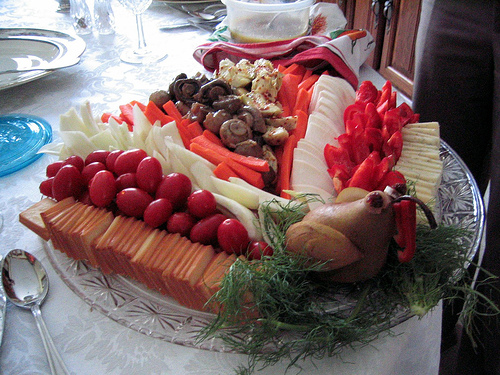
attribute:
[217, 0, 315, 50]
container — clear plastic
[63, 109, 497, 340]
platter — large, glass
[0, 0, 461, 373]
table cloth — white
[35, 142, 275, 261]
olives — red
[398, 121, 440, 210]
cheese — sliced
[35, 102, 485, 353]
platter — clear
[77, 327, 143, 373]
table cloth — white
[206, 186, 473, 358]
garnish — green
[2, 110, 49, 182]
blue lid — plastic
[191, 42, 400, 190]
veggies — sliced up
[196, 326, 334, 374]
dill — fresh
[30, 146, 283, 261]
tomatoes — red